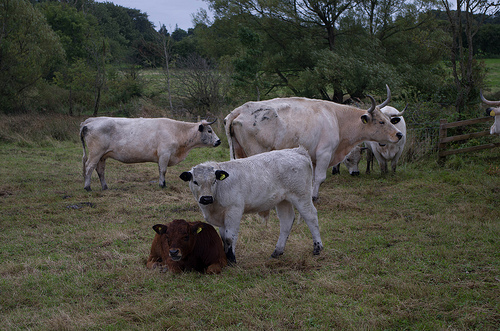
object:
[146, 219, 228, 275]
cow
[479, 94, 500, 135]
cows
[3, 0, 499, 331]
pasture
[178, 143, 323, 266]
cow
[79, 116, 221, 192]
cows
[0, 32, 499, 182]
back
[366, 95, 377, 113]
horns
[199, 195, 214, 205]
nose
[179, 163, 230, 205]
head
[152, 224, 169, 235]
ears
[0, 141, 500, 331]
grass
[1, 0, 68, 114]
trees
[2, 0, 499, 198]
background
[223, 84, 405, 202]
cow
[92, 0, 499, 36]
sky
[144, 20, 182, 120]
tree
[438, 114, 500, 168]
fence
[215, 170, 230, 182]
ears